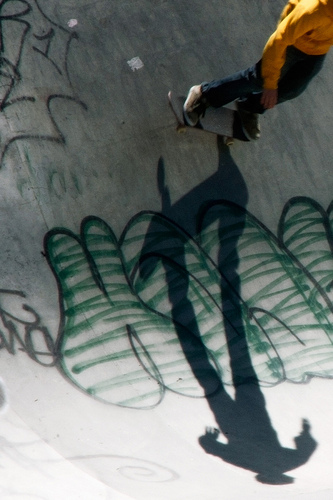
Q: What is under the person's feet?
A: A skateboard.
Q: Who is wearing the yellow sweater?
A: The skateboarder.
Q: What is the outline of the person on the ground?
A: A shadow.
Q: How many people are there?
A: 1.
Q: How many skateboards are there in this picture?
A: 1.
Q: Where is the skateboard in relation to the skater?
A: Underneath.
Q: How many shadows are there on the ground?
A: 1.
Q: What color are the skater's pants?
A: Blue.